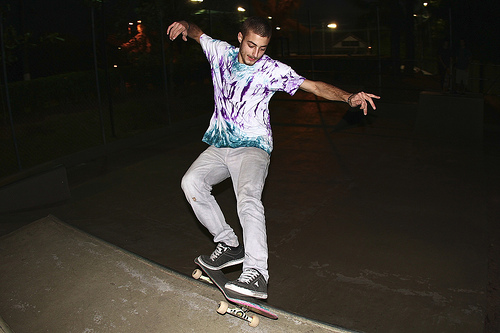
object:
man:
[163, 12, 381, 301]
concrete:
[0, 214, 351, 333]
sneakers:
[224, 269, 270, 300]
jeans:
[180, 144, 270, 284]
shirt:
[196, 32, 305, 156]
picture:
[0, 1, 497, 333]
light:
[328, 22, 338, 29]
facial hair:
[241, 52, 262, 66]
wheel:
[191, 269, 202, 280]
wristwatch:
[347, 93, 356, 105]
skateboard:
[191, 255, 278, 328]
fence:
[1, 0, 170, 179]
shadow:
[212, 186, 224, 192]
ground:
[0, 85, 500, 333]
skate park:
[0, 0, 500, 333]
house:
[331, 31, 370, 54]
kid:
[436, 36, 457, 96]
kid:
[451, 35, 473, 97]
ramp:
[415, 89, 485, 146]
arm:
[292, 68, 378, 116]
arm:
[167, 20, 221, 52]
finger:
[366, 93, 381, 99]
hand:
[347, 90, 381, 116]